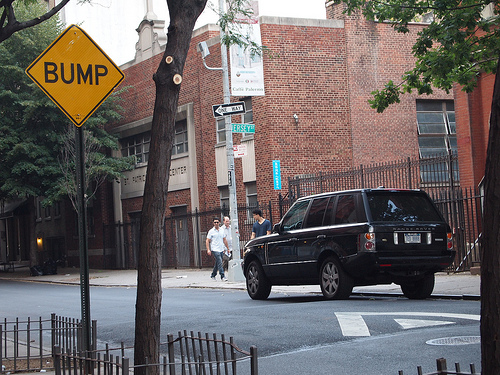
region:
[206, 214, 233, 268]
the guy is walking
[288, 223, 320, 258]
the vehicle is black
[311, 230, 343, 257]
the vehicle is parked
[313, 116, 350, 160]
the building is made of bricks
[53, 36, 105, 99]
the sign is yellow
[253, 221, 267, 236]
the shirt is blue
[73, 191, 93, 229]
the post is green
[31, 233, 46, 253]
the light is on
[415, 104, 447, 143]
the window is open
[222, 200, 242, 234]
the pole is gray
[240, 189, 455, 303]
a black SUV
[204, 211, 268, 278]
people walking on sidewalk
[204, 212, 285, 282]
people talking on sidewalk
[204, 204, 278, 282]
people standing on sidewalk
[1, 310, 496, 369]
a short picket fence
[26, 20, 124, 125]
a yellow road sign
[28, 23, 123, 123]
a sign that says bump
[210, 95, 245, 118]
a one way traffic sign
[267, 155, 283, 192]
a blue banner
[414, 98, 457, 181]
windows slightly open on building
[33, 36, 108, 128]
a yellow sign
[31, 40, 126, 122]
a yellow street sign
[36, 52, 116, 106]
the word bump is written on the yellow sign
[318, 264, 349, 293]
back wheel of the car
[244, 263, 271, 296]
front tire of the vehicle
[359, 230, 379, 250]
left back taillight of the car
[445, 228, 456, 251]
right back taillight of the car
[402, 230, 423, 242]
a license plate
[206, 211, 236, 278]
a group of people walking in the sidewalk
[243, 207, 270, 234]
a man in blue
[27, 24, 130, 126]
diamond shaped yellow hazard sign reading "BUMP"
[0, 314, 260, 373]
short wrought iron fencing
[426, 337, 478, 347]
round metal manhole cover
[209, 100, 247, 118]
white arrow on black square reading "ONE WAY"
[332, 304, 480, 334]
white triangular lines marking pavenment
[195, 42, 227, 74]
grey surveillance camera on post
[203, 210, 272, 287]
group of men standing on sidewalk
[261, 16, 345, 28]
grey concrete roof trim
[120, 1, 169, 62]
white wooden building roof adornment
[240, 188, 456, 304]
somewhat clean black SUV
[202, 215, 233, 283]
two people walking on the sidewalk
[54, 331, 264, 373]
a fence around a tree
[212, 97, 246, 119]
one way sign on a pole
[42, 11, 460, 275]
a red brick building across the street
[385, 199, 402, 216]
sticker on window of SUV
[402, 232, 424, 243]
rear license tag on the SUV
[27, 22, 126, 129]
diamond shaped yellow and black sign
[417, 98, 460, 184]
a set of open windows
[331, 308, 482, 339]
lane markings in the roadway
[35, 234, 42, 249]
a light in the shade